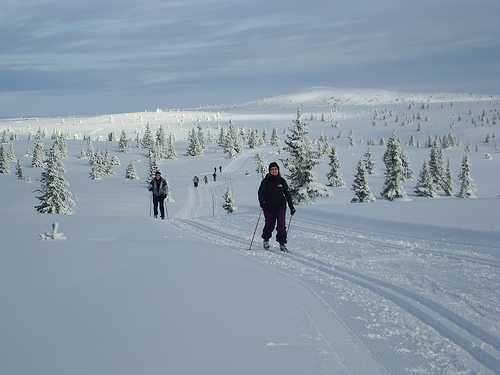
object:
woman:
[258, 162, 297, 253]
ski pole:
[248, 208, 263, 250]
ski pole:
[286, 215, 293, 235]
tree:
[34, 143, 75, 216]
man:
[148, 171, 169, 220]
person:
[193, 176, 199, 187]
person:
[212, 172, 216, 181]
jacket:
[258, 173, 294, 212]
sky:
[0, 0, 499, 118]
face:
[270, 167, 278, 176]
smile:
[271, 170, 276, 173]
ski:
[218, 210, 345, 256]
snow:
[1, 254, 500, 373]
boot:
[263, 241, 270, 251]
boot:
[280, 244, 288, 252]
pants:
[261, 209, 287, 244]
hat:
[269, 162, 280, 173]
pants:
[153, 196, 166, 217]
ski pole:
[150, 191, 153, 217]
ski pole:
[165, 201, 170, 219]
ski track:
[175, 215, 498, 374]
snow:
[350, 159, 376, 202]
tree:
[351, 157, 376, 203]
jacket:
[148, 176, 168, 197]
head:
[269, 162, 280, 175]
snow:
[32, 141, 82, 217]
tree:
[456, 153, 478, 198]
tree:
[0, 147, 9, 175]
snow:
[455, 158, 478, 199]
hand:
[291, 208, 296, 214]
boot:
[161, 217, 165, 220]